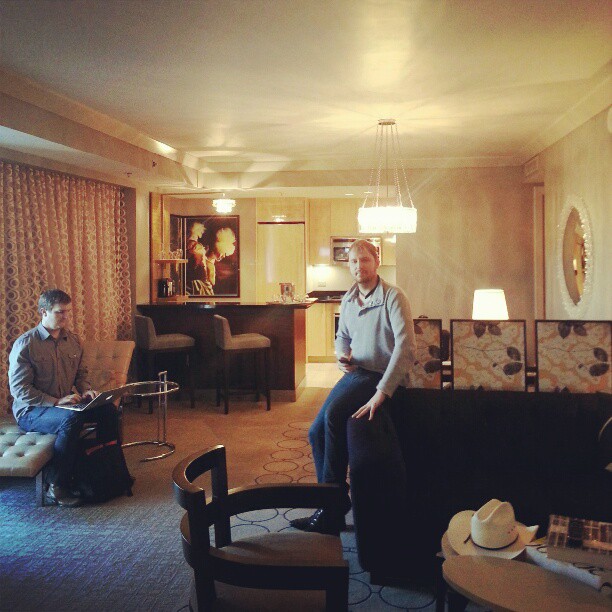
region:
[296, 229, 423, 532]
man holding black remote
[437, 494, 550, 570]
white cowboy hat on the table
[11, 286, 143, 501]
man using laptop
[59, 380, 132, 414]
open silver laptop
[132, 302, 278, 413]
two chairs at the bar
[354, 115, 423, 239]
light fixture hanging from the ceiling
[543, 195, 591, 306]
mirror with white frame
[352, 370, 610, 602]
black couch the man is sitting on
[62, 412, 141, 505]
black backpack against the man legs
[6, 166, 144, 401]
curtains behind the man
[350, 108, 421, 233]
a hanging chandelier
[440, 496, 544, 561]
a white cowboy hat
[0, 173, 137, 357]
a large decorative curtain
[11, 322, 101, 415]
a man's long sleeve shirt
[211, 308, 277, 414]
a tall stool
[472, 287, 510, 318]
a white lampshade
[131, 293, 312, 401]
a tall brown bar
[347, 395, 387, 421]
the hand of a man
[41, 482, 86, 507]
a man's brown shoe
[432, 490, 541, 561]
cowboy hat on table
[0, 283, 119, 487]
man sitting on sofa on his laptop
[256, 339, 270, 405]
wood leg on bar stool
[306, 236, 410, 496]
man sitting on chair holding his phone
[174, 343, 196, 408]
wood leg on bar stool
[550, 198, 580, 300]
white mirror on white wall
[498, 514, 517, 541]
holes in side of cowboy hat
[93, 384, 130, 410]
apple logo on silver laptop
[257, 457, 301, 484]
black circles on grey rug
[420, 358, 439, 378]
leaf design on partition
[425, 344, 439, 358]
leaf design on partition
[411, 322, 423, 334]
leaf design on partition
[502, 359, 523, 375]
leaf design on partition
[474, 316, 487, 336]
leaf design on partition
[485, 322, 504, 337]
leaf design on partition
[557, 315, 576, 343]
leaf design on partition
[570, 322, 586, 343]
leaf design on partition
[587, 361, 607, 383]
leaf design on partition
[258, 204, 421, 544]
the man has blonde hair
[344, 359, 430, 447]
the hand is touching sofa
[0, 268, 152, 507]
the man is working on computer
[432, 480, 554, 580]
the hat is white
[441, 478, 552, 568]
the hat is a cowboy hat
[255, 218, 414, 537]
the man is sitting on side of sofa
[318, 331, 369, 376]
the hand holds remote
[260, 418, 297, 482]
the tiles are round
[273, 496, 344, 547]
the shoes are black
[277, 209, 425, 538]
man seated down halfway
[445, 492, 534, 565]
cowboy hat on seat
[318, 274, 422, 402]
grey colored shirt on man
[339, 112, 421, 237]
large light fixture on ceiling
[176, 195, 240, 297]
huge painting in the background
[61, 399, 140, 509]
black colored backpack of the man sitting down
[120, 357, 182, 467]
metal prong object on the floor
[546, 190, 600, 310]
circular hole on the wall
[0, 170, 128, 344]
pink colored curtains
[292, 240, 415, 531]
Man leaning against the couch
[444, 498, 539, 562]
Cowboy hat is tan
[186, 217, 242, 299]
Painting hung on the wall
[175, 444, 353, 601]
Chair is dark wood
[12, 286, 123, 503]
Man sitting on bench